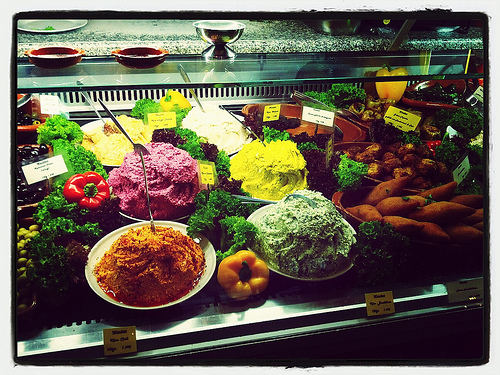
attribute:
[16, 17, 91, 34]
plate — empty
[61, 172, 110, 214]
pepper — large red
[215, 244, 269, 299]
pepper — yellow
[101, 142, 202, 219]
gelatin salad — pink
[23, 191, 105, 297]
green food — Decorative 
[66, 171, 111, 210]
bellpepper — bell 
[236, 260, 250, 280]
green stem — green 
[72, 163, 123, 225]
pepper — red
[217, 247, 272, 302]
bell pepper — yellow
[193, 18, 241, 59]
bowl — silver, measuring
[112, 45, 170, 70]
bowl — brown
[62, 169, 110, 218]
pepper — bell, red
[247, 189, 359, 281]
salad — green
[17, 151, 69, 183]
sign — white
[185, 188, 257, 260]
kale — garnish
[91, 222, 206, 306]
food item — orange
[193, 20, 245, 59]
bowl — silver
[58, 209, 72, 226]
leaves — green 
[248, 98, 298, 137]
writing — black